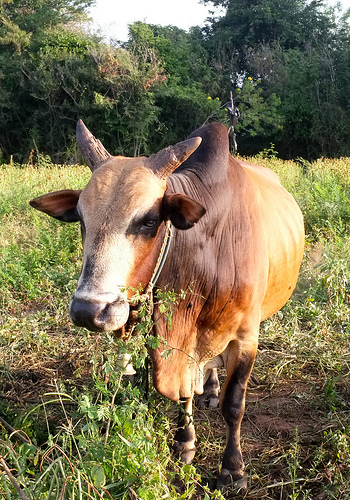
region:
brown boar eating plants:
[74, 283, 175, 370]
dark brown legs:
[175, 358, 263, 493]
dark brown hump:
[179, 112, 241, 289]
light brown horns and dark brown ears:
[27, 117, 205, 236]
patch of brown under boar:
[144, 372, 314, 490]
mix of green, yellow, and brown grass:
[5, 156, 349, 498]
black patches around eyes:
[135, 209, 162, 237]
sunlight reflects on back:
[243, 169, 306, 335]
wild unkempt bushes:
[7, 324, 229, 497]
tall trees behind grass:
[0, 0, 349, 157]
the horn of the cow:
[142, 129, 207, 179]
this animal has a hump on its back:
[175, 116, 240, 184]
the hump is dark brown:
[160, 115, 238, 188]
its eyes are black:
[132, 213, 161, 234]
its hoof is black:
[220, 467, 255, 496]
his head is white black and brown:
[68, 145, 172, 339]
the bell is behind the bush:
[114, 338, 138, 381]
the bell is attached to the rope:
[109, 330, 144, 380]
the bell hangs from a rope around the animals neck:
[116, 219, 182, 385]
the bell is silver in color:
[111, 349, 139, 380]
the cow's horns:
[73, 115, 198, 175]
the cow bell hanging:
[114, 351, 135, 372]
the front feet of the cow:
[172, 431, 244, 481]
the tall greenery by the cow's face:
[36, 332, 195, 499]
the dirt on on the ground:
[251, 388, 305, 439]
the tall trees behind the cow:
[10, 6, 346, 126]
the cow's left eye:
[136, 217, 158, 231]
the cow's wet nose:
[67, 299, 93, 327]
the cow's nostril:
[95, 304, 110, 323]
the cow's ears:
[28, 189, 206, 229]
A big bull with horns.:
[28, 117, 305, 497]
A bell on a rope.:
[114, 219, 174, 376]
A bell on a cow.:
[114, 218, 174, 376]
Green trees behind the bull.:
[1, 0, 349, 164]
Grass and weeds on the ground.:
[2, 151, 347, 499]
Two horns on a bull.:
[75, 118, 202, 181]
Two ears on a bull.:
[28, 189, 208, 231]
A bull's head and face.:
[68, 155, 166, 333]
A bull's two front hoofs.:
[170, 439, 249, 497]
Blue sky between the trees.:
[51, 0, 348, 89]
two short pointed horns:
[65, 106, 203, 175]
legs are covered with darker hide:
[176, 350, 260, 485]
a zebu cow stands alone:
[23, 116, 311, 499]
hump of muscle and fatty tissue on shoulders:
[160, 108, 243, 188]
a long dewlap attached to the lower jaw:
[130, 294, 225, 412]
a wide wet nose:
[62, 286, 119, 331]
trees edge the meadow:
[0, 4, 72, 174]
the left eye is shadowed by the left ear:
[120, 187, 204, 243]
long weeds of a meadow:
[5, 161, 105, 498]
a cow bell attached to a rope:
[115, 219, 177, 379]